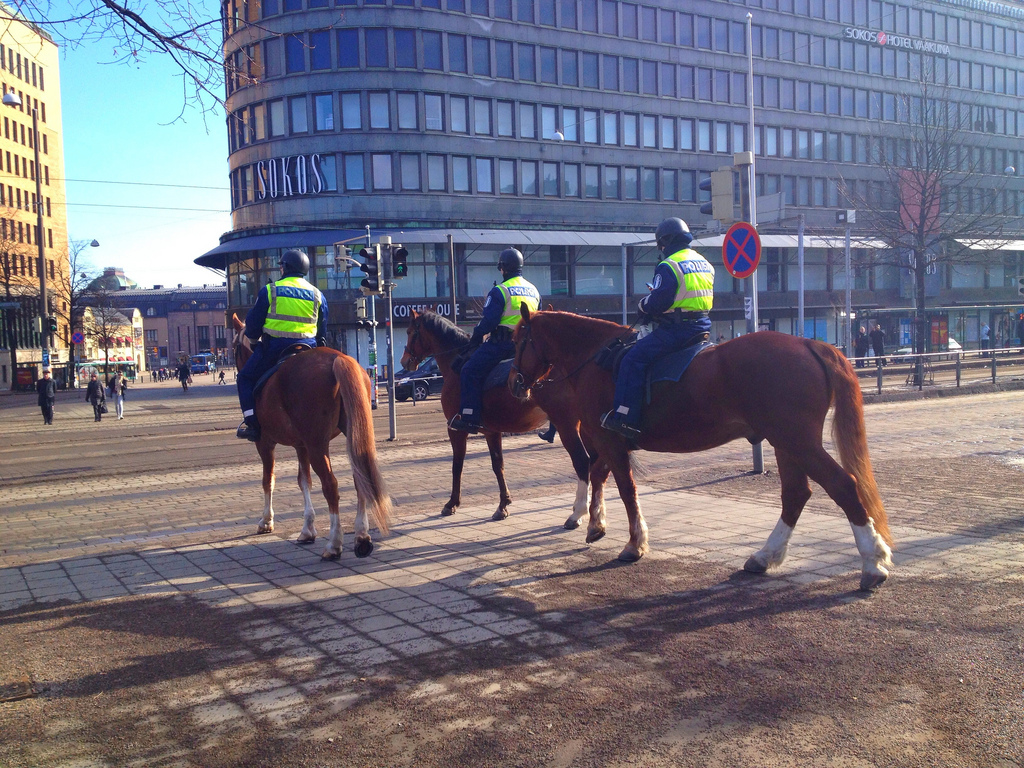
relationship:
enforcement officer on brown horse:
[607, 210, 716, 425] [510, 299, 900, 594]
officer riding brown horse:
[609, 203, 733, 391] [510, 301, 901, 592]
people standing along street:
[24, 351, 130, 428] [2, 360, 1022, 488]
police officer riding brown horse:
[596, 218, 718, 445] [219, 313, 400, 565]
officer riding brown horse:
[429, 244, 546, 441] [399, 304, 596, 529]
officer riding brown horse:
[597, 214, 718, 443] [510, 299, 900, 594]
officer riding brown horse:
[445, 248, 545, 436] [383, 297, 580, 533]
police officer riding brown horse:
[231, 231, 333, 446] [219, 299, 403, 557]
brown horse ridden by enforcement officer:
[219, 299, 403, 557] [259, 251, 324, 438]